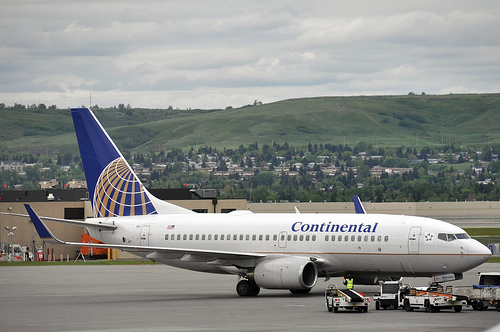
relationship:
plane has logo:
[0, 106, 494, 298] [290, 219, 379, 234]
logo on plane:
[290, 219, 379, 234] [0, 106, 494, 298]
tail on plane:
[70, 106, 159, 219] [0, 106, 494, 298]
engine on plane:
[253, 256, 319, 291] [0, 106, 494, 298]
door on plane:
[407, 225, 423, 254] [0, 106, 494, 298]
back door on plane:
[139, 223, 151, 249] [0, 106, 494, 298]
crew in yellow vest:
[340, 273, 354, 293] [346, 277, 355, 291]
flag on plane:
[166, 222, 176, 230] [0, 106, 494, 298]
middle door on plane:
[277, 230, 290, 248] [0, 106, 494, 298]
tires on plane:
[235, 279, 313, 295] [0, 106, 494, 298]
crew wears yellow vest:
[340, 273, 354, 293] [346, 277, 355, 291]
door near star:
[407, 225, 423, 254] [424, 231, 434, 242]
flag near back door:
[166, 222, 176, 230] [139, 223, 151, 249]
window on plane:
[163, 233, 170, 241] [0, 106, 494, 298]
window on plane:
[170, 233, 177, 241] [0, 106, 494, 298]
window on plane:
[175, 233, 181, 240] [0, 106, 494, 298]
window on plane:
[181, 232, 189, 242] [0, 106, 494, 298]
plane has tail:
[0, 106, 494, 298] [70, 106, 159, 219]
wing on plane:
[22, 201, 328, 267] [0, 106, 494, 298]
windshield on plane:
[438, 229, 472, 245] [0, 106, 494, 298]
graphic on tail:
[91, 154, 159, 217] [70, 106, 159, 219]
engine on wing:
[253, 256, 319, 291] [22, 201, 328, 267]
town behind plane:
[1, 150, 499, 201] [0, 106, 494, 298]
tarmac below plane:
[0, 261, 500, 331] [0, 106, 494, 298]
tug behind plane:
[77, 231, 109, 260] [0, 106, 494, 298]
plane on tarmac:
[0, 106, 494, 298] [0, 261, 500, 331]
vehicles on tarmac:
[324, 270, 499, 315] [0, 261, 500, 331]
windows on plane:
[163, 232, 390, 244] [0, 106, 494, 298]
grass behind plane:
[0, 257, 166, 268] [0, 106, 494, 298]